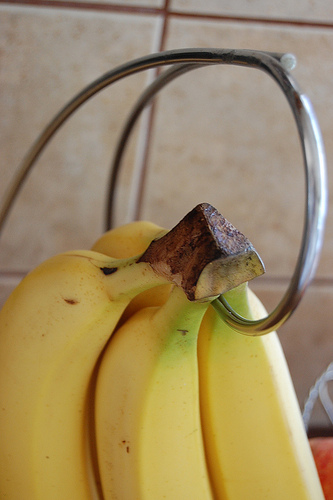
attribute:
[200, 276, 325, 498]
banana — ready